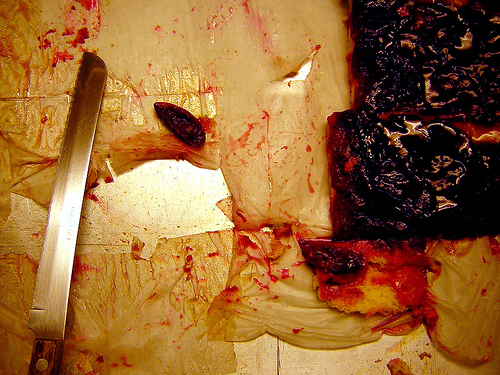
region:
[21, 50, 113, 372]
a serrated bread knife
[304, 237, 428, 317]
a piece of fruit dessert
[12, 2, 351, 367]
torn and stained wax paper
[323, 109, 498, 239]
a piece of fruit dessert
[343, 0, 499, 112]
a piece of fruit dessert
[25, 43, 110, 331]
the blade of a knife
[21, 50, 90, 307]
the edge of a knife blade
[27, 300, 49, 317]
a notch in the knife blade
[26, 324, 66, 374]
the wooden handle of a knife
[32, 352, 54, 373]
a bolt in the handle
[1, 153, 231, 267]
a gray metal table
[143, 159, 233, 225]
light shining on the table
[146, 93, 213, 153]
a large brown nut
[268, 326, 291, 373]
a crack in the table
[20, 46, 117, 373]
a large knife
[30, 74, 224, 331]
the knife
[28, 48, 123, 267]
the knife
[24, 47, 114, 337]
a metal knife blade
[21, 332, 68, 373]
a wooden knife handle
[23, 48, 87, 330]
the edge of the knife blade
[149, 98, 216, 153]
a black and brown pit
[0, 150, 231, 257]
a metal table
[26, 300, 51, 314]
a notch in the blade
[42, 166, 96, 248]
light shining on the blade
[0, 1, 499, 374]
meat is murder. but this may be pomegranates.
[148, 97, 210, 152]
slice of pomegranate atop bloodlike spattered table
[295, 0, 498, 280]
splotchy dark purple -things- that are either carnivore or herbivore oriented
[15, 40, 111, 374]
knife is big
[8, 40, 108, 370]
knife is probably bread knife, maybe boning knife [boning knife would have curved back]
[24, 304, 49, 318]
knife has notch in blade. [no. of murders? only one?]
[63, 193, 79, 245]
knife has maker's name on side opposite blade's edge.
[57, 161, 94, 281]
maker's name is unintelligible due to reflection of light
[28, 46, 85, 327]
knife has serrated blade edge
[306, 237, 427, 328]
potential piece of pound cake beneath pomegranate slice, bottom right, mired in blood or, rather, fruit sauce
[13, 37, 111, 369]
large serrated bread knife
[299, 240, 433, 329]
piece of pastry with jelly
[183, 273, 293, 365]
torn and sticky tissue paper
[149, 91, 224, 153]
small slice of plum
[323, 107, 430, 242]
purple plum coffee cake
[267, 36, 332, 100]
torn tissue paper on counter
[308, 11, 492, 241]
large section of jelly topped pastry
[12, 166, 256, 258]
large rip in the tissue paper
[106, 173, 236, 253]
counter top with sticky jelly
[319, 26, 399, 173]
piece of pastry cut into sections